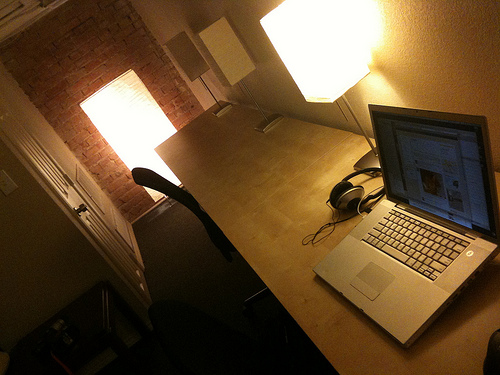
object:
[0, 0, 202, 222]
brick wall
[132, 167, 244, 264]
chair back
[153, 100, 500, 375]
table surface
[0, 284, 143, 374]
end table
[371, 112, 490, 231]
screen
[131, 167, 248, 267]
chair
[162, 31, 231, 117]
lamp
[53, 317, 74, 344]
container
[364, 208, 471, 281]
keyboard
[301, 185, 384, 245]
wire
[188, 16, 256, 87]
light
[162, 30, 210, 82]
light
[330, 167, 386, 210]
headphones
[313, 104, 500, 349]
computer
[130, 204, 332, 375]
flooring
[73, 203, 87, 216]
door knob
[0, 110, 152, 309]
door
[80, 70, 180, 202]
doorway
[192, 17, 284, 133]
lamp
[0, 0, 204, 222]
brick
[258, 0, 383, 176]
lamps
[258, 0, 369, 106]
lights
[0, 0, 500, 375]
wall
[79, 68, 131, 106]
panel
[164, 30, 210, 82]
shade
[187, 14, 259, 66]
shade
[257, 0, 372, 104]
shade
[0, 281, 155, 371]
area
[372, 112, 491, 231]
monitor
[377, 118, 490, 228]
information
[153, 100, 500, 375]
desk